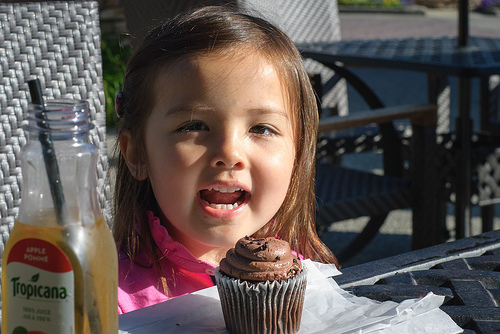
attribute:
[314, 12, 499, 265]
patio — concrete